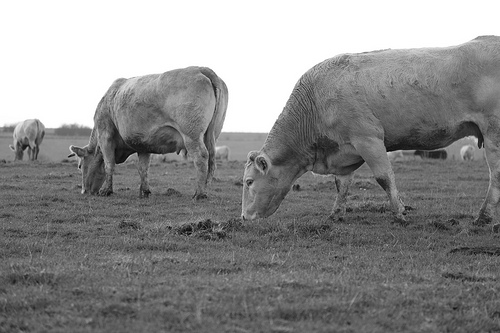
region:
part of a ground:
[198, 231, 240, 281]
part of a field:
[168, 210, 210, 265]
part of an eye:
[243, 160, 264, 220]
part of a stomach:
[423, 129, 443, 150]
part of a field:
[200, 243, 237, 285]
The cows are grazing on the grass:
[47, 44, 484, 229]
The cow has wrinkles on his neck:
[277, 87, 350, 159]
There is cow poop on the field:
[167, 215, 235, 247]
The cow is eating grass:
[220, 137, 292, 226]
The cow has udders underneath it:
[164, 137, 201, 169]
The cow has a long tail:
[205, 61, 222, 175]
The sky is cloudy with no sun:
[11, 17, 137, 58]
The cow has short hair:
[357, 46, 423, 97]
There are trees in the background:
[45, 116, 105, 146]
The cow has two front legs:
[307, 142, 464, 222]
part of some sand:
[176, 217, 215, 275]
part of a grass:
[224, 259, 266, 318]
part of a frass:
[201, 262, 234, 294]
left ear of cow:
[253, 150, 295, 181]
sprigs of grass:
[33, 229, 139, 288]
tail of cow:
[197, 61, 248, 122]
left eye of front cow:
[240, 171, 267, 198]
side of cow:
[376, 65, 471, 127]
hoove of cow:
[98, 174, 124, 199]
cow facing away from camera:
[8, 117, 67, 163]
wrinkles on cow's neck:
[273, 109, 355, 153]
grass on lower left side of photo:
[0, 230, 112, 330]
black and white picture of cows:
[24, 69, 496, 324]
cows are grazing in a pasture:
[1, 9, 498, 323]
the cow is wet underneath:
[276, 115, 498, 177]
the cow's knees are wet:
[329, 170, 398, 200]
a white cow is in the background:
[453, 137, 479, 167]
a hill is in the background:
[5, 117, 495, 199]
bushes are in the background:
[2, 117, 90, 141]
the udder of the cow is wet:
[168, 131, 197, 163]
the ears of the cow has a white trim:
[244, 145, 271, 177]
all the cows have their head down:
[11, 72, 493, 257]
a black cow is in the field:
[406, 147, 449, 164]